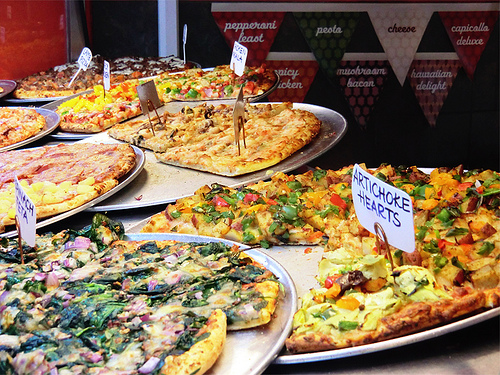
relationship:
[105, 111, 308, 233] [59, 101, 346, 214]
pizza on tray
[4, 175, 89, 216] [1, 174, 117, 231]
toppings on pizza slice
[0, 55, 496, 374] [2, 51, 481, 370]
pizza pies on display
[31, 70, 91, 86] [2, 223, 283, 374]
meat on pizza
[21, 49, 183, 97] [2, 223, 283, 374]
cheese on pizza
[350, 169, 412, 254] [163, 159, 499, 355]
sign standing up on pizza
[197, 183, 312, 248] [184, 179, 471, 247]
toppings on pizza